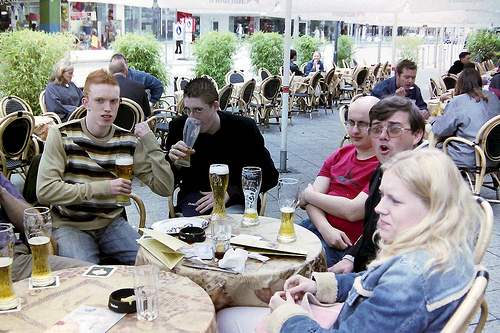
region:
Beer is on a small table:
[199, 157, 314, 249]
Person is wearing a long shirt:
[21, 63, 177, 250]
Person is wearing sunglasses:
[347, 92, 444, 184]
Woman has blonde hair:
[348, 142, 490, 298]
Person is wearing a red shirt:
[303, 133, 388, 254]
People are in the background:
[370, 60, 499, 119]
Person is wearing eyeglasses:
[334, 116, 370, 138]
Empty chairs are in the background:
[228, 54, 415, 105]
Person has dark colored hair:
[181, 68, 225, 140]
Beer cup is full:
[198, 153, 234, 227]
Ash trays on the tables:
[108, 223, 204, 316]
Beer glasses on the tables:
[0, 164, 305, 314]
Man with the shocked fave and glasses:
[364, 93, 426, 167]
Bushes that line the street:
[0, 19, 497, 106]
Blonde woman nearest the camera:
[216, 145, 488, 332]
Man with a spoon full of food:
[367, 60, 434, 122]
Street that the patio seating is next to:
[50, 39, 470, 91]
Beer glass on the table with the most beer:
[204, 165, 231, 225]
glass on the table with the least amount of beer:
[238, 164, 265, 234]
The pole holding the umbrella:
[273, 4, 309, 171]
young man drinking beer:
[34, 71, 171, 261]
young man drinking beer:
[164, 66, 280, 221]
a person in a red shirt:
[290, 95, 391, 261]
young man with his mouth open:
[367, 98, 427, 160]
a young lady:
[269, 147, 483, 332]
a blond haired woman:
[269, 147, 481, 332]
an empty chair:
[226, 68, 246, 83]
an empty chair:
[257, 65, 273, 80]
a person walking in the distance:
[169, 15, 186, 60]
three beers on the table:
[207, 163, 304, 243]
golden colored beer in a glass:
[15, 201, 69, 292]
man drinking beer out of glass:
[163, 78, 239, 190]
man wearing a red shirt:
[321, 83, 377, 235]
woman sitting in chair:
[350, 152, 491, 327]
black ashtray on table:
[95, 273, 147, 324]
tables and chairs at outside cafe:
[214, 65, 328, 112]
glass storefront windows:
[65, 3, 234, 65]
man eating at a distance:
[395, 58, 435, 105]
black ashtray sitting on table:
[167, 218, 215, 262]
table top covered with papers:
[137, 217, 310, 299]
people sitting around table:
[32, 76, 499, 331]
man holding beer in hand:
[35, 60, 184, 255]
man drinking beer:
[164, 61, 306, 246]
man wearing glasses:
[355, 92, 437, 202]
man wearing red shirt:
[301, 98, 393, 287]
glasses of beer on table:
[192, 150, 320, 270]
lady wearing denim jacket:
[246, 137, 473, 330]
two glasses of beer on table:
[0, 198, 79, 322]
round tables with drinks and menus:
[132, 184, 355, 331]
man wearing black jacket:
[171, 71, 278, 226]